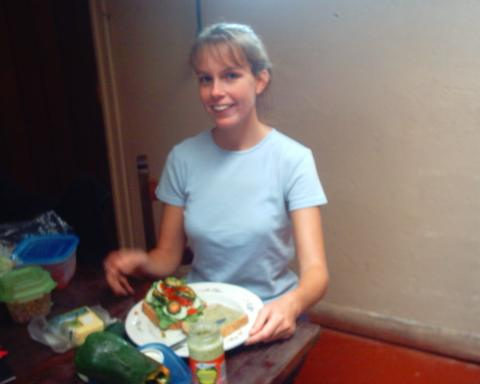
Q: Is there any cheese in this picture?
A: Yes, there is cheese.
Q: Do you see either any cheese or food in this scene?
A: Yes, there is cheese.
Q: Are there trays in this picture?
A: No, there are no trays.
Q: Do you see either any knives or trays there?
A: No, there are no trays or knives.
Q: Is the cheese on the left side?
A: Yes, the cheese is on the left of the image.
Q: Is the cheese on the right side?
A: No, the cheese is on the left of the image.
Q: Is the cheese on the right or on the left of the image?
A: The cheese is on the left of the image.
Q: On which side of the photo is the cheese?
A: The cheese is on the left of the image.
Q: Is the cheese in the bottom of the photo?
A: Yes, the cheese is in the bottom of the image.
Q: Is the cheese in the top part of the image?
A: No, the cheese is in the bottom of the image.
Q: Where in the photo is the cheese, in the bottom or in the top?
A: The cheese is in the bottom of the image.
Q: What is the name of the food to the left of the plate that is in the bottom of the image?
A: The food is cheese.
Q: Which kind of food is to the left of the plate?
A: The food is cheese.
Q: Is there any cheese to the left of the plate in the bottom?
A: Yes, there is cheese to the left of the plate.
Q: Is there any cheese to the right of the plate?
A: No, the cheese is to the left of the plate.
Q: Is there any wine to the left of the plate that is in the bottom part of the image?
A: No, there is cheese to the left of the plate.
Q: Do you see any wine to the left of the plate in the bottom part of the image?
A: No, there is cheese to the left of the plate.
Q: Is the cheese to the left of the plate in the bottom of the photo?
A: Yes, the cheese is to the left of the plate.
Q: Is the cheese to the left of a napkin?
A: No, the cheese is to the left of the plate.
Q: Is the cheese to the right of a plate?
A: No, the cheese is to the left of a plate.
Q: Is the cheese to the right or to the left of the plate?
A: The cheese is to the left of the plate.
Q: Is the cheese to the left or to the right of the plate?
A: The cheese is to the left of the plate.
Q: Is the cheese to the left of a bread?
A: Yes, the cheese is to the left of a bread.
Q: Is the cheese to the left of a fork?
A: No, the cheese is to the left of a bread.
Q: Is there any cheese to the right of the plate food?
A: No, the cheese is to the left of the food.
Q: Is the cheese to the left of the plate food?
A: Yes, the cheese is to the left of the food.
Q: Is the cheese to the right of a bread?
A: No, the cheese is to the left of a bread.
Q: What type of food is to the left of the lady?
A: The food is cheese.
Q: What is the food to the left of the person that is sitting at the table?
A: The food is cheese.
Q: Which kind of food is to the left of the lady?
A: The food is cheese.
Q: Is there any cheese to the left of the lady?
A: Yes, there is cheese to the left of the lady.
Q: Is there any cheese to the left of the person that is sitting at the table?
A: Yes, there is cheese to the left of the lady.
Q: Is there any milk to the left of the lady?
A: No, there is cheese to the left of the lady.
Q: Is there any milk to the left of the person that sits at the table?
A: No, there is cheese to the left of the lady.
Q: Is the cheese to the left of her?
A: Yes, the cheese is to the left of the lady.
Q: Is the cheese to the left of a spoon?
A: No, the cheese is to the left of the lady.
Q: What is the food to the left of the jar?
A: The food is cheese.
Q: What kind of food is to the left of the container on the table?
A: The food is cheese.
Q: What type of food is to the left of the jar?
A: The food is cheese.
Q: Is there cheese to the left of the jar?
A: Yes, there is cheese to the left of the jar.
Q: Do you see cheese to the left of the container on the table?
A: Yes, there is cheese to the left of the jar.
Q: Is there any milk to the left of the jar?
A: No, there is cheese to the left of the jar.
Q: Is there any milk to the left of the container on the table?
A: No, there is cheese to the left of the jar.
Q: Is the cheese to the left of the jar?
A: Yes, the cheese is to the left of the jar.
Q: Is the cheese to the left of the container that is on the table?
A: Yes, the cheese is to the left of the jar.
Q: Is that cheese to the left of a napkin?
A: No, the cheese is to the left of the jar.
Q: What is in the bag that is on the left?
A: The cheese is in the bag.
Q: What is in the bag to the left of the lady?
A: The cheese is in the bag.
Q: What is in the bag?
A: The cheese is in the bag.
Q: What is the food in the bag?
A: The food is cheese.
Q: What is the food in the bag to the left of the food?
A: The food is cheese.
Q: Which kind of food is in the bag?
A: The food is cheese.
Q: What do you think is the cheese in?
A: The cheese is in the bag.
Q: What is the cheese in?
A: The cheese is in the bag.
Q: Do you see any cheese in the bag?
A: Yes, there is cheese in the bag.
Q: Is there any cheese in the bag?
A: Yes, there is cheese in the bag.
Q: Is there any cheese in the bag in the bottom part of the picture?
A: Yes, there is cheese in the bag.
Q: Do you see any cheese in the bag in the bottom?
A: Yes, there is cheese in the bag.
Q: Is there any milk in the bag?
A: No, there is cheese in the bag.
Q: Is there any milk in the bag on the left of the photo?
A: No, there is cheese in the bag.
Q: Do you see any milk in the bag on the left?
A: No, there is cheese in the bag.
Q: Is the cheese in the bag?
A: Yes, the cheese is in the bag.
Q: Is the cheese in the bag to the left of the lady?
A: Yes, the cheese is in the bag.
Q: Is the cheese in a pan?
A: No, the cheese is in the bag.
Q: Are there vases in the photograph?
A: No, there are no vases.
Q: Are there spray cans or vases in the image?
A: No, there are no vases or spray cans.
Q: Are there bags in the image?
A: Yes, there is a bag.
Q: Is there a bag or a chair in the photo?
A: Yes, there is a bag.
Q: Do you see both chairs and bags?
A: Yes, there are both a bag and a chair.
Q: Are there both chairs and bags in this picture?
A: Yes, there are both a bag and a chair.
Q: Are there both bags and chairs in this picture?
A: Yes, there are both a bag and a chair.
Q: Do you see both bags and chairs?
A: Yes, there are both a bag and a chair.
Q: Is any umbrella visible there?
A: No, there are no umbrellas.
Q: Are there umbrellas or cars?
A: No, there are no umbrellas or cars.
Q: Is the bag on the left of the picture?
A: Yes, the bag is on the left of the image.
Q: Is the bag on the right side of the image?
A: No, the bag is on the left of the image.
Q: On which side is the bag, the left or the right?
A: The bag is on the left of the image.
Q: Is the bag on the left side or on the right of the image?
A: The bag is on the left of the image.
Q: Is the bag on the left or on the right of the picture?
A: The bag is on the left of the image.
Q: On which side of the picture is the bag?
A: The bag is on the left of the image.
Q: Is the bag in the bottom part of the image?
A: Yes, the bag is in the bottom of the image.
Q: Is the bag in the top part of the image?
A: No, the bag is in the bottom of the image.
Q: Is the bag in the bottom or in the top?
A: The bag is in the bottom of the image.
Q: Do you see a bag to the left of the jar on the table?
A: Yes, there is a bag to the left of the jar.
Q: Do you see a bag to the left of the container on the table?
A: Yes, there is a bag to the left of the jar.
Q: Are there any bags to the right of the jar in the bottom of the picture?
A: No, the bag is to the left of the jar.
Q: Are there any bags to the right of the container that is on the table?
A: No, the bag is to the left of the jar.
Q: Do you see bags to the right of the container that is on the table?
A: No, the bag is to the left of the jar.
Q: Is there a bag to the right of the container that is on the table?
A: No, the bag is to the left of the jar.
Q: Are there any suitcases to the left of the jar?
A: No, there is a bag to the left of the jar.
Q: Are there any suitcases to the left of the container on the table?
A: No, there is a bag to the left of the jar.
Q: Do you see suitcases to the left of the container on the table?
A: No, there is a bag to the left of the jar.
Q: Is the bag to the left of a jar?
A: Yes, the bag is to the left of a jar.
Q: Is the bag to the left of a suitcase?
A: No, the bag is to the left of a jar.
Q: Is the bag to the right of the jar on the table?
A: No, the bag is to the left of the jar.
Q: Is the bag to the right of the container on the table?
A: No, the bag is to the left of the jar.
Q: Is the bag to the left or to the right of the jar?
A: The bag is to the left of the jar.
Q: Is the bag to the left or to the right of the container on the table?
A: The bag is to the left of the jar.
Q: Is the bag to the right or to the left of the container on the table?
A: The bag is to the left of the jar.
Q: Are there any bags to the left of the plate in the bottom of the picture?
A: Yes, there is a bag to the left of the plate.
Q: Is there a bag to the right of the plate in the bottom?
A: No, the bag is to the left of the plate.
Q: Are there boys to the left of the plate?
A: No, there is a bag to the left of the plate.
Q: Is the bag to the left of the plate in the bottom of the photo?
A: Yes, the bag is to the left of the plate.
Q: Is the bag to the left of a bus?
A: No, the bag is to the left of the plate.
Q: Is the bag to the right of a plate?
A: No, the bag is to the left of a plate.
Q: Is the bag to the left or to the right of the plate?
A: The bag is to the left of the plate.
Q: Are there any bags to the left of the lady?
A: Yes, there is a bag to the left of the lady.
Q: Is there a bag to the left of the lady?
A: Yes, there is a bag to the left of the lady.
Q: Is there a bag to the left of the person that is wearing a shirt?
A: Yes, there is a bag to the left of the lady.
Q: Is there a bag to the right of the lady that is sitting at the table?
A: No, the bag is to the left of the lady.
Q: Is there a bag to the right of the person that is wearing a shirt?
A: No, the bag is to the left of the lady.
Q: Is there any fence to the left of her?
A: No, there is a bag to the left of the lady.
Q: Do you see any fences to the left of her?
A: No, there is a bag to the left of the lady.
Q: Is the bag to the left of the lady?
A: Yes, the bag is to the left of the lady.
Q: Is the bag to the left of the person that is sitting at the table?
A: Yes, the bag is to the left of the lady.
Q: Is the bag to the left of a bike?
A: No, the bag is to the left of the lady.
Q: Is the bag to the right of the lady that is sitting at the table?
A: No, the bag is to the left of the lady.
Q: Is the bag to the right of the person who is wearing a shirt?
A: No, the bag is to the left of the lady.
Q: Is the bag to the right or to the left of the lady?
A: The bag is to the left of the lady.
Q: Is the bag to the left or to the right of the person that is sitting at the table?
A: The bag is to the left of the lady.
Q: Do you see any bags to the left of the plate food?
A: Yes, there is a bag to the left of the food.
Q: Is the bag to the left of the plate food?
A: Yes, the bag is to the left of the food.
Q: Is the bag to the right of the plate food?
A: No, the bag is to the left of the food.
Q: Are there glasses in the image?
A: No, there are no glasses.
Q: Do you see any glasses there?
A: No, there are no glasses.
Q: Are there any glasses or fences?
A: No, there are no glasses or fences.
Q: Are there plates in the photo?
A: Yes, there is a plate.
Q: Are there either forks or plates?
A: Yes, there is a plate.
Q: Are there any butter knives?
A: No, there are no butter knives.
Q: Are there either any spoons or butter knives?
A: No, there are no butter knives or spoons.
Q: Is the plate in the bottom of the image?
A: Yes, the plate is in the bottom of the image.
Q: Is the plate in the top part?
A: No, the plate is in the bottom of the image.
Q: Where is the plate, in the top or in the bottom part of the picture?
A: The plate is in the bottom of the image.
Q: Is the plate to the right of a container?
A: Yes, the plate is to the right of a container.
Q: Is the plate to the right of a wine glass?
A: No, the plate is to the right of a container.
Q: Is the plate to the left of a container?
A: No, the plate is to the right of a container.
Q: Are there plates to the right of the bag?
A: Yes, there is a plate to the right of the bag.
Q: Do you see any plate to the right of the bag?
A: Yes, there is a plate to the right of the bag.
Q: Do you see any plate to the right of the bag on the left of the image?
A: Yes, there is a plate to the right of the bag.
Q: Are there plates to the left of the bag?
A: No, the plate is to the right of the bag.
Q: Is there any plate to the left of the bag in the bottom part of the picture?
A: No, the plate is to the right of the bag.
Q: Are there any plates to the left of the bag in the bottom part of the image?
A: No, the plate is to the right of the bag.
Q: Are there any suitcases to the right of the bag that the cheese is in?
A: No, there is a plate to the right of the bag.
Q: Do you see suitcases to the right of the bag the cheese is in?
A: No, there is a plate to the right of the bag.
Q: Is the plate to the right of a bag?
A: Yes, the plate is to the right of a bag.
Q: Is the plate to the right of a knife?
A: No, the plate is to the right of a bag.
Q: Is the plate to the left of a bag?
A: No, the plate is to the right of a bag.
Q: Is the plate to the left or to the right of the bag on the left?
A: The plate is to the right of the bag.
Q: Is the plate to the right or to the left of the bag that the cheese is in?
A: The plate is to the right of the bag.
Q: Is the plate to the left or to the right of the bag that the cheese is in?
A: The plate is to the right of the bag.